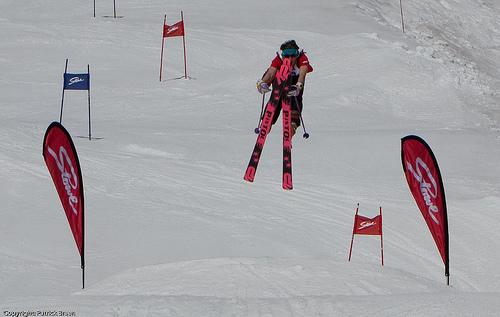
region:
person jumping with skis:
[235, 25, 322, 237]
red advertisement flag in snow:
[385, 105, 499, 302]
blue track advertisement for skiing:
[40, 40, 107, 141]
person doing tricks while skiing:
[42, 18, 446, 293]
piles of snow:
[372, 17, 485, 116]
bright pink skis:
[223, 23, 325, 220]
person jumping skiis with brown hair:
[235, 12, 335, 291]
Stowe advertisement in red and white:
[18, 112, 114, 249]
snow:
[160, 167, 249, 266]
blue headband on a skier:
[241, 22, 338, 209]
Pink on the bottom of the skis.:
[235, 41, 307, 200]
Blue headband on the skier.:
[275, 46, 312, 58]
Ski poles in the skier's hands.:
[229, 72, 321, 159]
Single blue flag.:
[39, 30, 126, 156]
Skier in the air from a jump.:
[206, 7, 336, 218]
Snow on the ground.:
[10, 0, 493, 310]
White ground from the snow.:
[23, 1, 493, 310]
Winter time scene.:
[5, 4, 495, 311]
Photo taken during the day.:
[11, 2, 496, 312]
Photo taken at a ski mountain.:
[6, 5, 493, 315]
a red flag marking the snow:
[29, 124, 114, 291]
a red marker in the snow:
[396, 126, 484, 309]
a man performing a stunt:
[219, 26, 320, 217]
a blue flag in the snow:
[49, 54, 114, 131]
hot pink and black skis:
[236, 71, 294, 190]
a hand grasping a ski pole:
[254, 80, 266, 138]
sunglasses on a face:
[281, 50, 296, 57]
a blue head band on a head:
[281, 48, 301, 55]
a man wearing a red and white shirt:
[255, 38, 310, 96]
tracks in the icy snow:
[420, 32, 470, 84]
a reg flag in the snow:
[389, 125, 479, 297]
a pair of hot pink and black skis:
[236, 71, 300, 195]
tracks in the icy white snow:
[154, 136, 204, 217]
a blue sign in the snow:
[51, 57, 113, 134]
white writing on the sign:
[69, 74, 87, 85]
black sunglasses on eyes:
[280, 49, 303, 60]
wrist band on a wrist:
[297, 83, 305, 90]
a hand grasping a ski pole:
[286, 86, 303, 99]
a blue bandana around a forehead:
[278, 44, 310, 58]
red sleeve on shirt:
[296, 57, 315, 65]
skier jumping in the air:
[211, 30, 321, 210]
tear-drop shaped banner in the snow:
[390, 120, 462, 282]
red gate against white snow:
[340, 190, 390, 266]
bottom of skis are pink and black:
[220, 100, 305, 190]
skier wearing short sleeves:
[251, 36, 318, 108]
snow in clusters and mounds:
[386, 5, 486, 101]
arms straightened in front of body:
[252, 35, 322, 125]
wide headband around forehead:
[261, 20, 302, 72]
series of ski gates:
[50, 0, 205, 131]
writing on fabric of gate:
[57, 65, 95, 93]